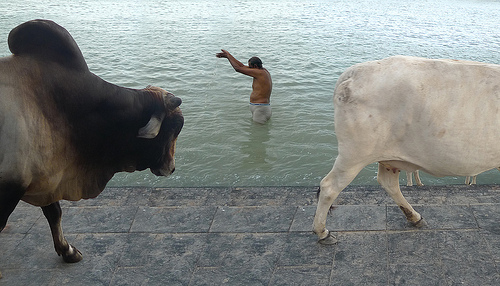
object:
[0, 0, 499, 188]
water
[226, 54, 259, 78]
arms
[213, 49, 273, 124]
man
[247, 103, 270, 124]
underware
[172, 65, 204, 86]
ripples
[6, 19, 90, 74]
hump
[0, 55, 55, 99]
back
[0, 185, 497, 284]
ground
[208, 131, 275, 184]
ripples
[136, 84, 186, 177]
head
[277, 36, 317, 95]
ripples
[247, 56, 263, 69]
head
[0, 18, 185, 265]
animal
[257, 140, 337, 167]
ripples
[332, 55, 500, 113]
rear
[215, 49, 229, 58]
hands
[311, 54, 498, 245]
animal